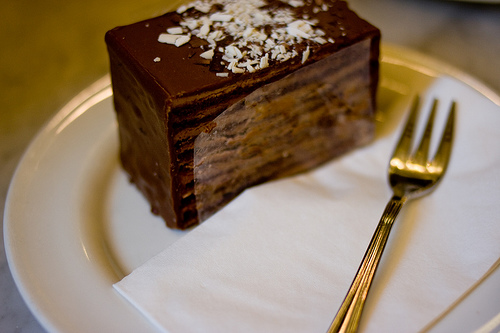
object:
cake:
[102, 0, 381, 228]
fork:
[326, 94, 459, 333]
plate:
[0, 43, 498, 332]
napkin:
[110, 75, 500, 333]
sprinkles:
[155, 32, 191, 48]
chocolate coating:
[101, 1, 383, 229]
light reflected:
[386, 156, 444, 174]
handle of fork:
[326, 197, 404, 332]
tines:
[383, 94, 457, 202]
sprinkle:
[152, 56, 163, 64]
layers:
[168, 31, 380, 233]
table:
[0, 1, 499, 332]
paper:
[193, 38, 370, 229]